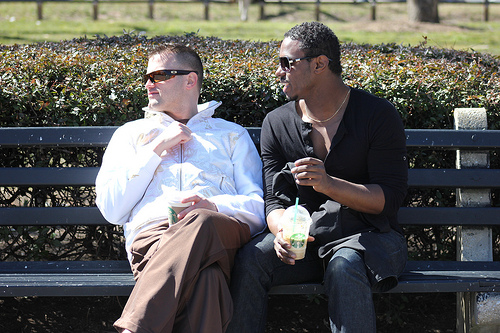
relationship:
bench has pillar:
[1, 106, 499, 331] [453, 106, 497, 332]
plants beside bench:
[1, 32, 499, 125] [1, 106, 499, 331]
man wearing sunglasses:
[232, 23, 412, 332] [277, 54, 317, 74]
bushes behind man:
[3, 34, 499, 264] [232, 23, 412, 332]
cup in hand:
[283, 198, 311, 260] [275, 222, 319, 268]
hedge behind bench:
[7, 49, 96, 114] [1, 106, 499, 331]